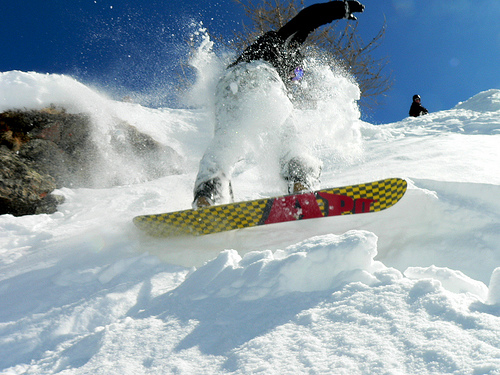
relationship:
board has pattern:
[132, 177, 407, 243] [149, 178, 400, 235]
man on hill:
[409, 94, 430, 117] [0, 68, 500, 375]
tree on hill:
[250, 12, 400, 137] [0, 68, 500, 375]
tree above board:
[250, 12, 400, 137] [132, 177, 407, 243]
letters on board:
[258, 191, 378, 225] [132, 177, 407, 243]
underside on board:
[168, 188, 402, 225] [132, 177, 407, 243]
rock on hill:
[0, 107, 188, 219] [0, 68, 500, 375]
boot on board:
[284, 160, 314, 202] [132, 177, 407, 243]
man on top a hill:
[409, 94, 430, 117] [0, 68, 500, 372]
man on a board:
[191, 0, 365, 210] [132, 177, 407, 243]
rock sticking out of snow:
[0, 107, 188, 219] [0, 57, 496, 372]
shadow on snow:
[126, 251, 336, 373] [273, 276, 429, 346]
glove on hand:
[348, 0, 364, 20] [286, 0, 409, 48]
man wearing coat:
[191, 0, 365, 210] [231, 30, 316, 85]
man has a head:
[405, 90, 429, 117] [412, 92, 424, 105]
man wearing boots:
[191, 0, 365, 210] [192, 158, 321, 205]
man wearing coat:
[191, 0, 365, 210] [226, 0, 344, 90]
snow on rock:
[0, 57, 496, 372] [0, 105, 205, 220]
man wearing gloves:
[191, 0, 365, 210] [342, 0, 363, 20]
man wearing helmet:
[409, 94, 430, 117] [413, 92, 421, 102]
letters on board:
[258, 188, 372, 224] [132, 177, 407, 243]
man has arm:
[191, 0, 365, 210] [266, 0, 366, 53]